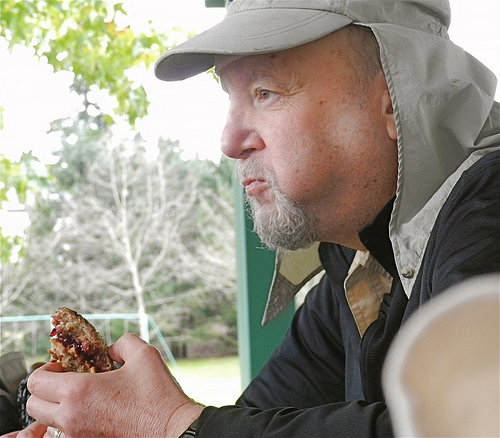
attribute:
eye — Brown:
[249, 83, 288, 108]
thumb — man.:
[104, 332, 158, 369]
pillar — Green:
[236, 195, 293, 389]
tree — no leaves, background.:
[40, 104, 229, 364]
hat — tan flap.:
[134, 4, 471, 102]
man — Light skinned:
[300, 117, 364, 207]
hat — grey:
[152, 2, 497, 102]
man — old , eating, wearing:
[3, 2, 497, 434]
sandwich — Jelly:
[47, 302, 118, 373]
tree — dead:
[40, 149, 100, 217]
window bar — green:
[220, 0, 299, 409]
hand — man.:
[18, 323, 186, 430]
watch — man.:
[175, 406, 206, 436]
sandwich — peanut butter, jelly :
[46, 309, 116, 374]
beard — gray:
[237, 163, 331, 258]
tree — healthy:
[55, 154, 220, 332]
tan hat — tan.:
[175, 5, 480, 332]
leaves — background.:
[3, 5, 151, 118]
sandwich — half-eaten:
[15, 295, 167, 392]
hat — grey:
[150, 0, 474, 275]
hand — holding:
[21, 342, 187, 435]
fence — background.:
[0, 316, 53, 356]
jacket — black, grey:
[190, 149, 498, 436]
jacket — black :
[153, 166, 497, 436]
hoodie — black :
[161, 127, 497, 436]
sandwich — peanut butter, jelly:
[45, 301, 130, 394]